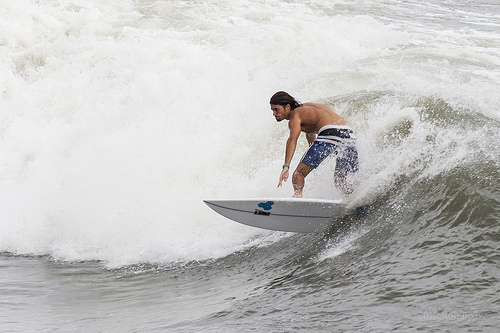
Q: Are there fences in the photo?
A: No, there are no fences.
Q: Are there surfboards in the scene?
A: Yes, there is a surfboard.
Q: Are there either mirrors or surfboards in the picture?
A: Yes, there is a surfboard.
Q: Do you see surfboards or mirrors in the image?
A: Yes, there is a surfboard.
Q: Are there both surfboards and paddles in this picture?
A: No, there is a surfboard but no paddles.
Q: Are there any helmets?
A: No, there are no helmets.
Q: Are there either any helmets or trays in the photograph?
A: No, there are no helmets or trays.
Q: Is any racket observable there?
A: No, there are no rackets.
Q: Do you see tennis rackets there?
A: No, there are no tennis rackets.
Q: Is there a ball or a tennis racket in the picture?
A: No, there are no rackets or balls.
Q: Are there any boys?
A: No, there are no boys.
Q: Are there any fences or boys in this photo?
A: No, there are no boys or fences.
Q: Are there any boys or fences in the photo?
A: No, there are no boys or fences.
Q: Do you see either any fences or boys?
A: No, there are no boys or fences.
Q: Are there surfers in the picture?
A: Yes, there is a surfer.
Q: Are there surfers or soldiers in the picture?
A: Yes, there is a surfer.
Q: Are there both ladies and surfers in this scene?
A: No, there is a surfer but no ladies.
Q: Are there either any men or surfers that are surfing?
A: Yes, the surfer is surfing.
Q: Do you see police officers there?
A: No, there are no police officers.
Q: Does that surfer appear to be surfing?
A: Yes, the surfer is surfing.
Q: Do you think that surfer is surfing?
A: Yes, the surfer is surfing.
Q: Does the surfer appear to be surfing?
A: Yes, the surfer is surfing.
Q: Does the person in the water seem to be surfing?
A: Yes, the surfer is surfing.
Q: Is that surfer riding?
A: No, the surfer is surfing.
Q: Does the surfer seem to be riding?
A: No, the surfer is surfing.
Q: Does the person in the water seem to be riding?
A: No, the surfer is surfing.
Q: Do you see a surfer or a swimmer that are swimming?
A: No, there is a surfer but he is surfing.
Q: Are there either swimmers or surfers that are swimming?
A: No, there is a surfer but he is surfing.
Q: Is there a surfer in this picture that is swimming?
A: No, there is a surfer but he is surfing.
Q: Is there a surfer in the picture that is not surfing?
A: No, there is a surfer but he is surfing.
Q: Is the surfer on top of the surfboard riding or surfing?
A: The surfer is surfing.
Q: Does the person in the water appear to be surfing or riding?
A: The surfer is surfing.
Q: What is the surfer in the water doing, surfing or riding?
A: The surfer is surfing.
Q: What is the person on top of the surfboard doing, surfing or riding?
A: The surfer is surfing.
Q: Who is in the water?
A: The surfer is in the water.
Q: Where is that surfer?
A: The surfer is in the water.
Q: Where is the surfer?
A: The surfer is in the water.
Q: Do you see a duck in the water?
A: No, there is a surfer in the water.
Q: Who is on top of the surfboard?
A: The surfer is on top of the surfboard.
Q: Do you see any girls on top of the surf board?
A: No, there is a surfer on top of the surf board.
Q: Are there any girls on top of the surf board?
A: No, there is a surfer on top of the surf board.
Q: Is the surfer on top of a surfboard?
A: Yes, the surfer is on top of a surfboard.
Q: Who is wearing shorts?
A: The surfer is wearing shorts.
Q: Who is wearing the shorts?
A: The surfer is wearing shorts.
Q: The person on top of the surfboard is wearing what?
A: The surfer is wearing shorts.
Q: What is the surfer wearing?
A: The surfer is wearing shorts.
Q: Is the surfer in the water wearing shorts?
A: Yes, the surfer is wearing shorts.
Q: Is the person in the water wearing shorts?
A: Yes, the surfer is wearing shorts.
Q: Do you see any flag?
A: No, there are no flags.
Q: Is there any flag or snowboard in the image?
A: No, there are no flags or snowboards.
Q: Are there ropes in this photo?
A: No, there are no ropes.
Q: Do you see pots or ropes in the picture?
A: No, there are no ropes or pots.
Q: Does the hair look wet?
A: Yes, the hair is wet.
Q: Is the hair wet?
A: Yes, the hair is wet.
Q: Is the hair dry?
A: No, the hair is wet.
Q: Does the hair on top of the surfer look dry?
A: No, the hair is wet.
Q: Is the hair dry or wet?
A: The hair is wet.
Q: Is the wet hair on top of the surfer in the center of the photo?
A: Yes, the hair is on top of the surfer.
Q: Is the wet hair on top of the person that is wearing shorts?
A: Yes, the hair is on top of the surfer.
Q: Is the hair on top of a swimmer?
A: No, the hair is on top of the surfer.